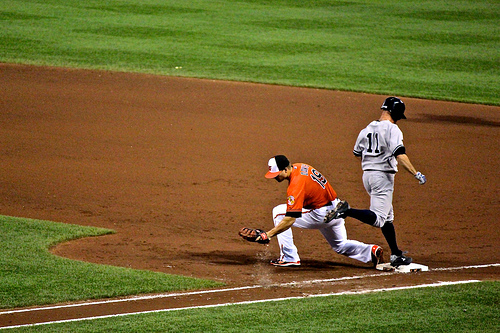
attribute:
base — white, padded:
[374, 255, 431, 274]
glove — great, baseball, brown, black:
[238, 223, 272, 248]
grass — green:
[184, 4, 429, 66]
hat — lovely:
[263, 153, 288, 180]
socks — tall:
[377, 221, 404, 256]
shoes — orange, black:
[266, 258, 305, 271]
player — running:
[361, 96, 419, 282]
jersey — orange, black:
[267, 168, 335, 205]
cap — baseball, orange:
[269, 159, 285, 172]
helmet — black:
[383, 89, 409, 115]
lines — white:
[144, 288, 222, 315]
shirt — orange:
[286, 175, 335, 202]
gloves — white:
[414, 169, 426, 191]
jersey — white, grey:
[356, 124, 404, 177]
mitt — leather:
[237, 224, 273, 250]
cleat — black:
[270, 257, 314, 273]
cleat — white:
[323, 199, 351, 221]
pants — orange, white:
[272, 210, 352, 257]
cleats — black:
[328, 201, 372, 239]